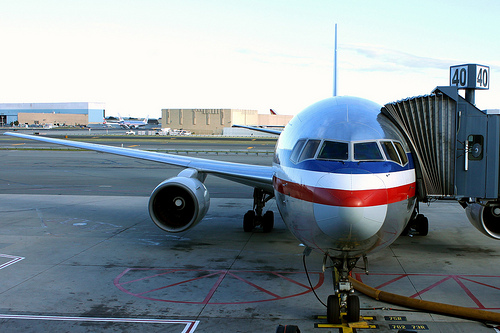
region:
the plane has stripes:
[261, 141, 438, 273]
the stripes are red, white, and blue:
[250, 136, 426, 228]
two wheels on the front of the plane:
[299, 288, 384, 330]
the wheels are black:
[307, 277, 363, 329]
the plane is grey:
[240, 64, 422, 259]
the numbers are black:
[432, 54, 489, 100]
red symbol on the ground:
[107, 253, 315, 315]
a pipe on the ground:
[331, 265, 486, 328]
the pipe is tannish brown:
[369, 290, 499, 323]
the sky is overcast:
[20, 9, 324, 103]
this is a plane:
[251, 103, 409, 302]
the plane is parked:
[251, 95, 421, 292]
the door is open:
[411, 88, 473, 199]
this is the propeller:
[151, 188, 205, 230]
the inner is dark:
[159, 189, 190, 216]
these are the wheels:
[315, 295, 368, 328]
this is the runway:
[183, 258, 258, 331]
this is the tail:
[318, 18, 347, 93]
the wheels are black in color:
[328, 298, 365, 320]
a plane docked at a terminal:
[177, 74, 473, 292]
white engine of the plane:
[124, 158, 244, 238]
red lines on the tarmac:
[102, 256, 311, 315]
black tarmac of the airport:
[28, 154, 124, 194]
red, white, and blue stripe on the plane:
[256, 149, 415, 219]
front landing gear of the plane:
[313, 262, 376, 325]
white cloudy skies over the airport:
[103, 16, 259, 81]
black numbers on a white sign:
[446, 66, 493, 87]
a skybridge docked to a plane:
[421, 61, 494, 199]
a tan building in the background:
[153, 100, 254, 138]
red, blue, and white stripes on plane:
[267, 154, 421, 215]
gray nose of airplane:
[298, 165, 400, 237]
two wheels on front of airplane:
[323, 289, 362, 324]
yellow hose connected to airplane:
[350, 270, 494, 331]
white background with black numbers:
[444, 60, 490, 92]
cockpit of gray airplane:
[286, 122, 406, 184]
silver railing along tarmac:
[131, 149, 271, 161]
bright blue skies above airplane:
[7, 19, 469, 81]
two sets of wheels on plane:
[235, 202, 430, 245]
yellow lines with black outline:
[310, 304, 381, 331]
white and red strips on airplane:
[273, 154, 416, 205]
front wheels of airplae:
[319, 282, 364, 319]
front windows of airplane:
[291, 133, 398, 172]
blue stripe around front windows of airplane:
[278, 144, 415, 174]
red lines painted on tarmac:
[115, 252, 498, 312]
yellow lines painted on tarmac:
[318, 310, 373, 331]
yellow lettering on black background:
[377, 310, 434, 330]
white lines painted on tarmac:
[4, 245, 205, 328]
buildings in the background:
[6, 97, 226, 142]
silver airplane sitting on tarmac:
[12, 84, 416, 269]